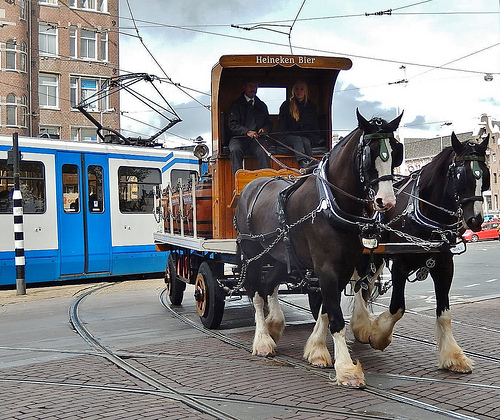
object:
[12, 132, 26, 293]
pole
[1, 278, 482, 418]
sidewalk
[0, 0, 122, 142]
brown building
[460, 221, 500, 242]
car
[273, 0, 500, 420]
right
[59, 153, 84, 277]
doors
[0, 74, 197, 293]
transit system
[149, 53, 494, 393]
carriage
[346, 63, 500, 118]
sky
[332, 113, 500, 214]
building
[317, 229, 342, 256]
skin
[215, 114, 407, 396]
horse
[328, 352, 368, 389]
feet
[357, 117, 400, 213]
face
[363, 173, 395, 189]
bridle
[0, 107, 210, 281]
train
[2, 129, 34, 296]
sign pole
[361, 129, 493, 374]
horses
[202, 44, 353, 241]
horse carriage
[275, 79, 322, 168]
people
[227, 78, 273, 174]
man